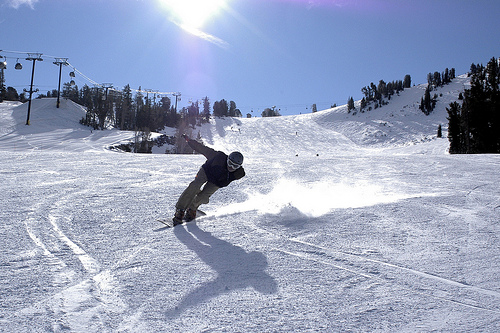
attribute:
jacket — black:
[204, 157, 237, 197]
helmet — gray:
[229, 145, 248, 164]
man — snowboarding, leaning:
[153, 126, 249, 243]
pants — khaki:
[179, 169, 211, 217]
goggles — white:
[225, 159, 239, 172]